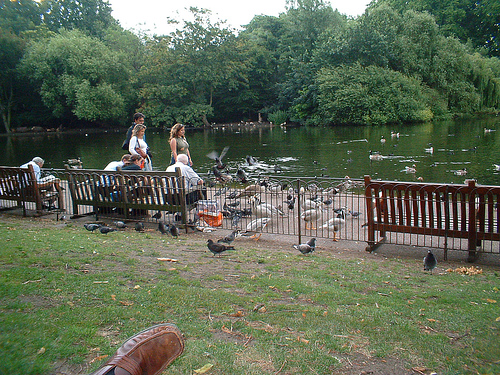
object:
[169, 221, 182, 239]
pigeons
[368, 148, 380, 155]
duck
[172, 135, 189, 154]
shirt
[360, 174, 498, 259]
bench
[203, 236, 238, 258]
pigeon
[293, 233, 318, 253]
pigeon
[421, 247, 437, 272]
pigeon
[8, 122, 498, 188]
lake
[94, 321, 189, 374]
shoe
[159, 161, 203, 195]
shirt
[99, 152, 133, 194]
man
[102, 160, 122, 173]
gray shirt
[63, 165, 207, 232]
bench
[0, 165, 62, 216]
bench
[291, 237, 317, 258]
bird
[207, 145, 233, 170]
bird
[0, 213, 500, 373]
grass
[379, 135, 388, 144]
ducks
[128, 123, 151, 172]
people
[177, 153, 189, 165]
white hair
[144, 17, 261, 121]
trees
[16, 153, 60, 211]
man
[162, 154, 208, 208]
man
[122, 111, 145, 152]
person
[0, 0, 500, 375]
park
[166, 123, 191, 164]
person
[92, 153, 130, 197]
person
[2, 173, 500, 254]
sidewalk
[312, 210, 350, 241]
bird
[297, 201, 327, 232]
bird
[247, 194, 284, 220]
bird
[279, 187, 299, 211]
bird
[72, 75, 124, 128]
trees